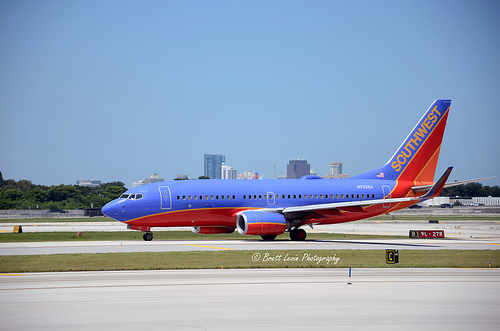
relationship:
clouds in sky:
[239, 87, 311, 131] [0, 6, 500, 156]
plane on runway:
[78, 87, 480, 257] [0, 232, 492, 260]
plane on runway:
[78, 87, 480, 257] [0, 264, 497, 329]